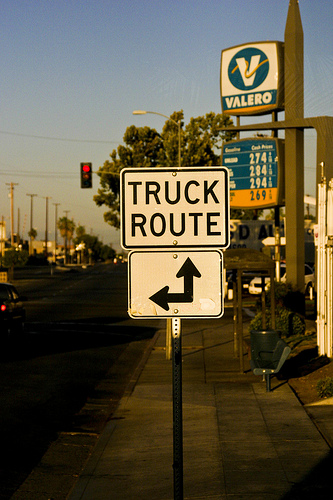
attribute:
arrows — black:
[149, 258, 200, 311]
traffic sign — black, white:
[121, 167, 230, 321]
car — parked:
[0, 282, 30, 332]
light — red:
[1, 304, 7, 313]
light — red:
[80, 160, 92, 174]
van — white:
[248, 261, 313, 304]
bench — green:
[250, 323, 289, 395]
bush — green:
[248, 281, 302, 347]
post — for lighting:
[133, 107, 183, 167]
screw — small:
[172, 253, 178, 257]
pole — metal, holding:
[172, 316, 184, 499]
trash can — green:
[251, 331, 280, 376]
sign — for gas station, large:
[216, 44, 281, 115]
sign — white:
[123, 169, 230, 249]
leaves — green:
[104, 113, 234, 165]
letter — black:
[185, 181, 202, 204]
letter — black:
[204, 178, 220, 203]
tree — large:
[94, 113, 234, 240]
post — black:
[172, 317, 182, 499]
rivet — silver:
[174, 252, 178, 259]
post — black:
[265, 376, 271, 390]